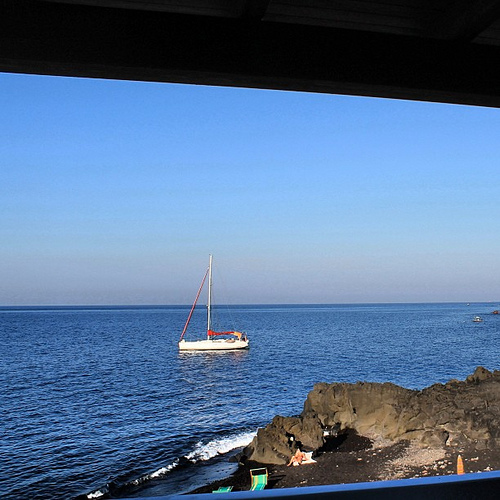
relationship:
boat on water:
[155, 232, 270, 364] [11, 311, 496, 434]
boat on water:
[171, 251, 248, 365] [0, 298, 490, 449]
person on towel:
[285, 441, 302, 467] [289, 449, 316, 470]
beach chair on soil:
[242, 460, 269, 492] [224, 460, 416, 495]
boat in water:
[171, 251, 248, 365] [38, 308, 178, 435]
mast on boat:
[181, 253, 221, 333] [171, 251, 248, 365]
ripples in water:
[128, 368, 241, 408] [15, 309, 498, 458]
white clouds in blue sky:
[0, 69, 498, 306] [1, 85, 498, 302]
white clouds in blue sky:
[305, 234, 371, 278] [1, 85, 498, 302]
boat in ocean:
[171, 251, 248, 365] [95, 371, 116, 389]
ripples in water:
[0, 303, 499, 499] [13, 359, 143, 466]